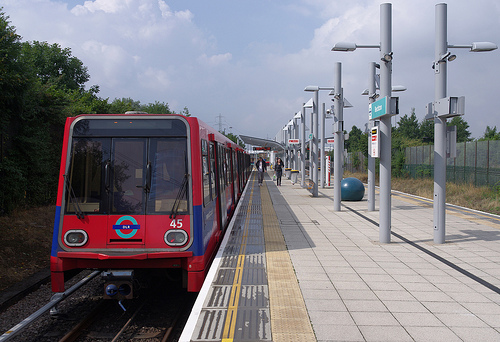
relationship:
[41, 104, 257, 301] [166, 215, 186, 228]
train has number 45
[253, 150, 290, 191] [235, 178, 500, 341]
people walking on platform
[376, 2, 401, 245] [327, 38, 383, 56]
posts has light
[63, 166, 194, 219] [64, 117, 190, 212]
wipers on windshield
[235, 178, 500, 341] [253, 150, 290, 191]
platform for passengers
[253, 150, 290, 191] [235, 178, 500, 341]
passengers walking down platform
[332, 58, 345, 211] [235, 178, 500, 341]
pole on platform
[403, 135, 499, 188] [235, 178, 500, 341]
fence along platform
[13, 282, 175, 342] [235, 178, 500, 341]
tracks near platform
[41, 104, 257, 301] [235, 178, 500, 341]
train in a terminal point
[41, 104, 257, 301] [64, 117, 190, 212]
train has windshield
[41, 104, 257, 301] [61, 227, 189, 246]
train has light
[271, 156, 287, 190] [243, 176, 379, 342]
person walking on sidewalk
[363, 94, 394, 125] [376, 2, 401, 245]
sign hanging on pole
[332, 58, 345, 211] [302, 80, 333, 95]
post of light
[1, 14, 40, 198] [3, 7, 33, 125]
tree with leaves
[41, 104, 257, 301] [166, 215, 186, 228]
train number 45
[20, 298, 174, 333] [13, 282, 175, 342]
gravel around tracks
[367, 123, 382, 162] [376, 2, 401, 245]
sign on post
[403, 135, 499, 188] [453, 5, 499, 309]
fence on right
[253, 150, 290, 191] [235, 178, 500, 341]
passenger boarding platform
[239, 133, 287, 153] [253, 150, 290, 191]
shelter for passenger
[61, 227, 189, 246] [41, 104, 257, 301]
headlight on front train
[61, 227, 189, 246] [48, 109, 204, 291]
headlight on front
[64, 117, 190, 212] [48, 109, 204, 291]
windshield on front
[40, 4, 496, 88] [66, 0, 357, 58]
clouds in sky